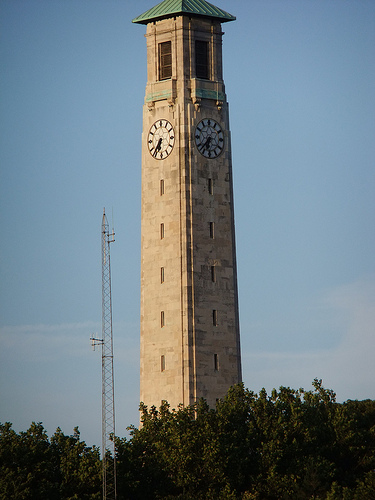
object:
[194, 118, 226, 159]
clock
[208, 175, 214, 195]
windows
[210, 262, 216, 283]
windows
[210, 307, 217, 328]
windows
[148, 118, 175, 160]
clock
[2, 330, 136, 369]
clouds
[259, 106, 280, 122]
sky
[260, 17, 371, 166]
sky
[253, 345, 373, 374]
clouds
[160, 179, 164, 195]
window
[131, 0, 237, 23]
roof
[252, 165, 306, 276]
sky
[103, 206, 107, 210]
point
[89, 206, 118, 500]
tower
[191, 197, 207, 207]
brick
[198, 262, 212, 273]
brick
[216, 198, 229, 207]
brick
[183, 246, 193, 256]
brick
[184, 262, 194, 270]
brick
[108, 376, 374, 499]
tree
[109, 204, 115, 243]
antenna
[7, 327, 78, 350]
clouds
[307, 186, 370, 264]
sky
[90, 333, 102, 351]
support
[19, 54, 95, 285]
sky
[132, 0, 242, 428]
structure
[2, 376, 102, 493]
trees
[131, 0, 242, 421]
tower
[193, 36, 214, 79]
window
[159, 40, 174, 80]
window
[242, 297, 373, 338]
clouds